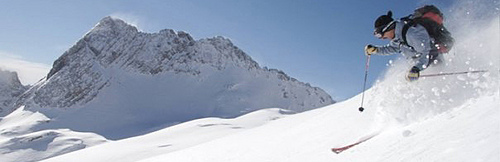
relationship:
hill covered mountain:
[0, 15, 338, 162] [7, 11, 333, 152]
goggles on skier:
[372, 18, 396, 40] [361, 2, 490, 89]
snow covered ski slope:
[175, 122, 275, 160] [3, 10, 483, 156]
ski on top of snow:
[322, 110, 407, 157] [10, 80, 487, 160]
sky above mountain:
[286, 14, 327, 66] [7, 11, 333, 152]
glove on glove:
[363, 44, 383, 55] [364, 44, 377, 55]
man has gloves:
[365, 5, 457, 82] [405, 66, 421, 81]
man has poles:
[365, 5, 457, 82] [357, 51, 489, 111]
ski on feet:
[332, 133, 381, 155] [399, 67, 444, 112]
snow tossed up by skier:
[39, 0, 500, 162] [363, 1, 455, 116]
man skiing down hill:
[365, 5, 457, 82] [18, 30, 485, 151]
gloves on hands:
[363, 42, 419, 80] [362, 42, 419, 81]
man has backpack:
[365, 5, 457, 82] [427, 1, 453, 58]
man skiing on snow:
[363, 9, 445, 79] [39, 0, 500, 162]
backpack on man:
[402, 3, 455, 66] [358, 5, 457, 136]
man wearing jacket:
[365, 5, 457, 82] [377, 20, 435, 68]